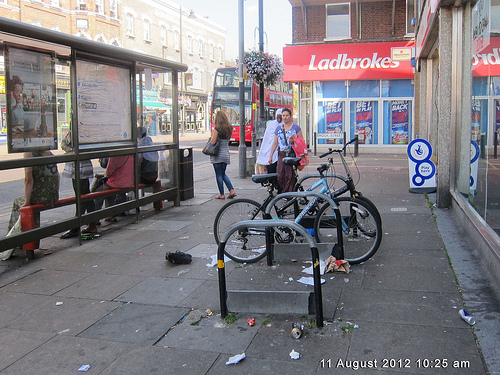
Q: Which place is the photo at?
A: It is at the sidewalk.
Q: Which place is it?
A: It is a sidewalk.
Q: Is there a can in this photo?
A: Yes, there is a can.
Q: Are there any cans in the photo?
A: Yes, there is a can.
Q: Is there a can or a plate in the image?
A: Yes, there is a can.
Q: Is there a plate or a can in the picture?
A: Yes, there is a can.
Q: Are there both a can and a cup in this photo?
A: No, there is a can but no cups.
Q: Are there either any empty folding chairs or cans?
A: Yes, there is an empty can.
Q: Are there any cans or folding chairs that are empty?
A: Yes, the can is empty.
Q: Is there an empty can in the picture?
A: Yes, there is an empty can.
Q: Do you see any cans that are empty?
A: Yes, there is a can that is empty.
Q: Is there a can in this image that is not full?
A: Yes, there is a empty can.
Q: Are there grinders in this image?
A: No, there are no grinders.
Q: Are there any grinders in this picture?
A: No, there are no grinders.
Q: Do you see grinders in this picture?
A: No, there are no grinders.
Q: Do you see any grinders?
A: No, there are no grinders.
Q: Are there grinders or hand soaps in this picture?
A: No, there are no grinders or hand soaps.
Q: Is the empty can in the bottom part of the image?
A: Yes, the can is in the bottom of the image.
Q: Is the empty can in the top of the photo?
A: No, the can is in the bottom of the image.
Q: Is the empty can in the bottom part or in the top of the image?
A: The can is in the bottom of the image.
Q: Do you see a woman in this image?
A: Yes, there is a woman.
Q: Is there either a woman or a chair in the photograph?
A: Yes, there is a woman.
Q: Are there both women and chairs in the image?
A: No, there is a woman but no chairs.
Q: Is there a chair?
A: No, there are no chairs.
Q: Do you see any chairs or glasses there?
A: No, there are no chairs or glasses.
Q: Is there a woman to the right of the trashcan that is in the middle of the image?
A: Yes, there is a woman to the right of the garbage can.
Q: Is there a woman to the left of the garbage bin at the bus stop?
A: No, the woman is to the right of the trashcan.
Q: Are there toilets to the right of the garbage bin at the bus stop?
A: No, there is a woman to the right of the trashcan.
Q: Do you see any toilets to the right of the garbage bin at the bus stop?
A: No, there is a woman to the right of the trashcan.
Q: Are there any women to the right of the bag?
A: Yes, there is a woman to the right of the bag.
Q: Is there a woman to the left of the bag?
A: No, the woman is to the right of the bag.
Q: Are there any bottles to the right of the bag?
A: No, there is a woman to the right of the bag.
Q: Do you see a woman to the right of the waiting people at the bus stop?
A: Yes, there is a woman to the right of the people.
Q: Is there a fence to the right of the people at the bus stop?
A: No, there is a woman to the right of the people.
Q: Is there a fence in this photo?
A: No, there are no fences.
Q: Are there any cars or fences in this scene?
A: No, there are no fences or cars.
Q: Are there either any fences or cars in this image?
A: No, there are no cars or fences.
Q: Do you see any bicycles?
A: Yes, there is a bicycle.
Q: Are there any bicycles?
A: Yes, there is a bicycle.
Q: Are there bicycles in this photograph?
A: Yes, there is a bicycle.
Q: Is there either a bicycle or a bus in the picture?
A: Yes, there is a bicycle.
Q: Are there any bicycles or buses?
A: Yes, there is a bicycle.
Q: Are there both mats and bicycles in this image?
A: No, there is a bicycle but no mats.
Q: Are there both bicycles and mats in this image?
A: No, there is a bicycle but no mats.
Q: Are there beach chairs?
A: No, there are no beach chairs.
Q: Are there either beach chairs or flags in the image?
A: No, there are no beach chairs or flags.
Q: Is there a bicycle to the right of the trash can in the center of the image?
A: Yes, there is a bicycle to the right of the trashcan.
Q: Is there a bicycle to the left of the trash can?
A: No, the bicycle is to the right of the trash can.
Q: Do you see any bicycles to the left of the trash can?
A: No, the bicycle is to the right of the trash can.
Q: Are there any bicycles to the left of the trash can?
A: No, the bicycle is to the right of the trash can.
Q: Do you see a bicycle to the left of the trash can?
A: No, the bicycle is to the right of the trash can.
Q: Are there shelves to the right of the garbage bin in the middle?
A: No, there is a bicycle to the right of the garbage bin.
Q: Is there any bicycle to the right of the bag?
A: Yes, there is a bicycle to the right of the bag.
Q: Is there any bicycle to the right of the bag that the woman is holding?
A: Yes, there is a bicycle to the right of the bag.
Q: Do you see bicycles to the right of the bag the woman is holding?
A: Yes, there is a bicycle to the right of the bag.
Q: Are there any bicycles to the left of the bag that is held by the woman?
A: No, the bicycle is to the right of the bag.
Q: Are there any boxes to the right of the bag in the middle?
A: No, there is a bicycle to the right of the bag.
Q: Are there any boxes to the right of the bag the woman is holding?
A: No, there is a bicycle to the right of the bag.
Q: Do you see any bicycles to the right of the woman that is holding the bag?
A: Yes, there is a bicycle to the right of the woman.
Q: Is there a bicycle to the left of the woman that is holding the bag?
A: No, the bicycle is to the right of the woman.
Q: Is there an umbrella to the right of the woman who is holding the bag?
A: No, there is a bicycle to the right of the woman.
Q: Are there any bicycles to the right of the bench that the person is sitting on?
A: Yes, there is a bicycle to the right of the bench.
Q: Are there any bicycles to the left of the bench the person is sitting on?
A: No, the bicycle is to the right of the bench.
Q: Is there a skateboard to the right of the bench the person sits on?
A: No, there is a bicycle to the right of the bench.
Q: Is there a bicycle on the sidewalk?
A: Yes, there is a bicycle on the sidewalk.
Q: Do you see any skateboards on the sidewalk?
A: No, there is a bicycle on the sidewalk.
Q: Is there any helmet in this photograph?
A: No, there are no helmets.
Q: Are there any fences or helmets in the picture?
A: No, there are no helmets or fences.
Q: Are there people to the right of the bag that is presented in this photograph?
A: No, the person is to the left of the bag.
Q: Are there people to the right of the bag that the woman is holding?
A: No, the person is to the left of the bag.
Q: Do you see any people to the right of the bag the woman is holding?
A: No, the person is to the left of the bag.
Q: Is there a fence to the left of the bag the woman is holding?
A: No, there is a person to the left of the bag.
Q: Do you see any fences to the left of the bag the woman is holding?
A: No, there is a person to the left of the bag.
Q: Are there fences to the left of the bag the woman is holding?
A: No, there is a person to the left of the bag.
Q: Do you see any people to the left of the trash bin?
A: Yes, there is a person to the left of the trash bin.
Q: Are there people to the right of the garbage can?
A: No, the person is to the left of the garbage can.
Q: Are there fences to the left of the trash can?
A: No, there is a person to the left of the trash can.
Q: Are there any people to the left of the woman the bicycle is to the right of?
A: Yes, there is a person to the left of the woman.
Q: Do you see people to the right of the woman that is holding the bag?
A: No, the person is to the left of the woman.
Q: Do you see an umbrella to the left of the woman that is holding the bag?
A: No, there is a person to the left of the woman.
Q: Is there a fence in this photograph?
A: No, there are no fences.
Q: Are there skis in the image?
A: No, there are no skis.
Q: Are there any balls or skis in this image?
A: No, there are no skis or balls.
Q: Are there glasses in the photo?
A: No, there are no glasses.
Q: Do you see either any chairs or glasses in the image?
A: No, there are no glasses or chairs.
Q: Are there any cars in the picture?
A: No, there are no cars.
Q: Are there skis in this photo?
A: No, there are no skis.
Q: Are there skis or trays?
A: No, there are no skis or trays.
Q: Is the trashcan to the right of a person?
A: Yes, the trashcan is to the right of a person.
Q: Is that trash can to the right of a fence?
A: No, the trash can is to the right of a person.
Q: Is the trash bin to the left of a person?
A: No, the trash bin is to the right of a person.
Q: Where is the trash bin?
A: The trash bin is at the bus stop.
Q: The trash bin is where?
A: The trash bin is at the bus stop.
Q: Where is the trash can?
A: The trash bin is at the bus stop.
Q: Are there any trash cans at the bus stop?
A: Yes, there is a trash can at the bus stop.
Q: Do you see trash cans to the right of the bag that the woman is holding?
A: No, the trash can is to the left of the bag.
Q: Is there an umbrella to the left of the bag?
A: No, there is a trash can to the left of the bag.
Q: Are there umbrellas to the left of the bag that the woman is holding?
A: No, there is a trash can to the left of the bag.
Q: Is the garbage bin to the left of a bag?
A: Yes, the garbage bin is to the left of a bag.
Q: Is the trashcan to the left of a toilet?
A: No, the trashcan is to the left of a bag.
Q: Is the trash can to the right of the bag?
A: No, the trash can is to the left of the bag.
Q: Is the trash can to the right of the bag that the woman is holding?
A: No, the trash can is to the left of the bag.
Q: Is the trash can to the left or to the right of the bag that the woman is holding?
A: The trash can is to the left of the bag.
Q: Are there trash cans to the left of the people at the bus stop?
A: Yes, there is a trash can to the left of the people.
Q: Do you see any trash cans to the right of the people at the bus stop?
A: No, the trash can is to the left of the people.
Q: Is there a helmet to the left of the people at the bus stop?
A: No, there is a trash can to the left of the people.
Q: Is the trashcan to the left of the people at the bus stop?
A: Yes, the trashcan is to the left of the people.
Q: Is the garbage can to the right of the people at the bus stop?
A: No, the garbage can is to the left of the people.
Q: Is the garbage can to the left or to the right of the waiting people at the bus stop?
A: The garbage can is to the left of the people.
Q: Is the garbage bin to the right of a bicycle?
A: No, the garbage bin is to the left of a bicycle.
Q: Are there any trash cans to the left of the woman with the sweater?
A: Yes, there is a trash can to the left of the woman.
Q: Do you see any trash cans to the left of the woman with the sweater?
A: Yes, there is a trash can to the left of the woman.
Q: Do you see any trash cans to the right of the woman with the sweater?
A: No, the trash can is to the left of the woman.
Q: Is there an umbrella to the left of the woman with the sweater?
A: No, there is a trash can to the left of the woman.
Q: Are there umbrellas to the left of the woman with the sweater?
A: No, there is a trash can to the left of the woman.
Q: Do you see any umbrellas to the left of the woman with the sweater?
A: No, there is a trash can to the left of the woman.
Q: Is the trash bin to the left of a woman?
A: Yes, the trash bin is to the left of a woman.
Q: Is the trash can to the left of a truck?
A: No, the trash can is to the left of a woman.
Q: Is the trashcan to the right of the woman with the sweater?
A: No, the trashcan is to the left of the woman.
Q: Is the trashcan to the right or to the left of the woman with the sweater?
A: The trashcan is to the left of the woman.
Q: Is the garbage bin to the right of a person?
A: Yes, the garbage bin is to the right of a person.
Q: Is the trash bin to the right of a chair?
A: No, the trash bin is to the right of a person.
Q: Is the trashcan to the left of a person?
A: No, the trashcan is to the right of a person.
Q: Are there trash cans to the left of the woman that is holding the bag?
A: Yes, there is a trash can to the left of the woman.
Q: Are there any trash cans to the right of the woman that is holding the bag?
A: No, the trash can is to the left of the woman.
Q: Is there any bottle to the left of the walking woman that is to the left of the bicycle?
A: No, there is a trash can to the left of the woman.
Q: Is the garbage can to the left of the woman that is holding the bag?
A: Yes, the garbage can is to the left of the woman.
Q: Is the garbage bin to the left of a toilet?
A: No, the garbage bin is to the left of the woman.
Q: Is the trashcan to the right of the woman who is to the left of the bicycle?
A: No, the trashcan is to the left of the woman.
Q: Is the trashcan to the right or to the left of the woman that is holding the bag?
A: The trashcan is to the left of the woman.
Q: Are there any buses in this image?
A: Yes, there is a bus.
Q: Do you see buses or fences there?
A: Yes, there is a bus.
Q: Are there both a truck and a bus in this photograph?
A: No, there is a bus but no trucks.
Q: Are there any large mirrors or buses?
A: Yes, there is a large bus.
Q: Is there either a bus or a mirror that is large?
A: Yes, the bus is large.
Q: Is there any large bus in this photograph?
A: Yes, there is a large bus.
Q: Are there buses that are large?
A: Yes, there is a bus that is large.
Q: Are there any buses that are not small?
A: Yes, there is a large bus.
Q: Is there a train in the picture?
A: No, there are no trains.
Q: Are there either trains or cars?
A: No, there are no trains or cars.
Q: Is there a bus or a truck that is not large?
A: No, there is a bus but it is large.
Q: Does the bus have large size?
A: Yes, the bus is large.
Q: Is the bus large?
A: Yes, the bus is large.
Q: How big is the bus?
A: The bus is large.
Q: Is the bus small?
A: No, the bus is large.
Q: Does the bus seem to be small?
A: No, the bus is large.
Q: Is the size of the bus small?
A: No, the bus is large.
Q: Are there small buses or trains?
A: No, there is a bus but it is large.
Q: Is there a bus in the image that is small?
A: No, there is a bus but it is large.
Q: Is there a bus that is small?
A: No, there is a bus but it is large.